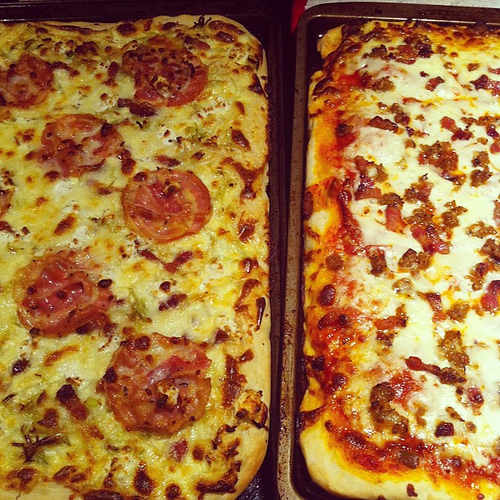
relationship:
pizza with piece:
[0, 14, 498, 499] [117, 168, 213, 243]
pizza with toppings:
[0, 14, 498, 499] [4, 37, 209, 438]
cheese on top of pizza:
[132, 122, 182, 162] [0, 14, 498, 499]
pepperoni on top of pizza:
[39, 114, 128, 179] [0, 14, 498, 499]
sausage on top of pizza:
[444, 200, 468, 229] [0, 14, 498, 499]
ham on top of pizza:
[412, 224, 449, 253] [0, 14, 498, 499]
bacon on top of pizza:
[354, 182, 384, 201] [0, 14, 498, 499]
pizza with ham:
[0, 14, 498, 499] [412, 224, 449, 253]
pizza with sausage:
[0, 14, 498, 499] [444, 200, 468, 229]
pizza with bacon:
[0, 14, 498, 499] [354, 182, 384, 201]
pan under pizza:
[273, 4, 499, 499] [0, 14, 498, 499]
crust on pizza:
[228, 17, 272, 499] [0, 14, 498, 499]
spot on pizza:
[231, 127, 252, 152] [0, 14, 498, 499]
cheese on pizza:
[132, 122, 182, 162] [0, 14, 498, 499]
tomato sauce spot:
[331, 133, 356, 149] [231, 127, 252, 152]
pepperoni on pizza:
[39, 114, 128, 179] [0, 14, 498, 499]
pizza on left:
[0, 14, 498, 499] [0, 0, 282, 499]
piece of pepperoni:
[117, 168, 213, 243] [39, 114, 128, 179]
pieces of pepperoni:
[5, 34, 216, 436] [39, 114, 128, 179]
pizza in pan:
[0, 14, 498, 499] [273, 4, 499, 499]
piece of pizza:
[117, 168, 213, 243] [0, 14, 498, 499]